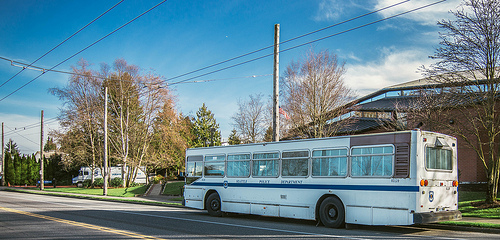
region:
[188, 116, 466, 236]
white bus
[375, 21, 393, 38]
white clouds in blue sky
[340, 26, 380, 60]
white clouds in blue sky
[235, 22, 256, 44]
white clouds in blue sky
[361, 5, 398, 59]
white clouds in blue sky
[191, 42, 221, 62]
white clouds in blue sky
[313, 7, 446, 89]
The sky is blue with some clouds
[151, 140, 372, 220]
The bus is parked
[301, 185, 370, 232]
The wheels are round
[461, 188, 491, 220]
The grass is green and short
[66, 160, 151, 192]
The truck is parked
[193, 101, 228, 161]
The tree is very tall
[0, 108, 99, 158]
The power lines are above the street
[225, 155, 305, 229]
The bus is mostly white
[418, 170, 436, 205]
The lights are off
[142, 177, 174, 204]
The walkway is concrete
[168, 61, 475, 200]
a bus on the road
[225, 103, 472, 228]
a bus on the street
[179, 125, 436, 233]
an old bus on the road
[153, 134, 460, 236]
an old bus on the street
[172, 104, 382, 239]
a white bus on the road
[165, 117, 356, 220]
a white bus on the street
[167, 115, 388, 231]
an old white bus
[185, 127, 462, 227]
a white passenger bus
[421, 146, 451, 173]
the rear window is closed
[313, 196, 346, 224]
the tire is black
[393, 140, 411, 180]
vents on the bus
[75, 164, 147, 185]
a white box truck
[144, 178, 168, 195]
a side walk by the grass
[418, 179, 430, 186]
tail lights on the bus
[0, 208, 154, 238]
a double yellow line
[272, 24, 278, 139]
a concrete pole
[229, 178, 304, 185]
blue lettering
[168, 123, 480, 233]
blue and white bus parked on the curb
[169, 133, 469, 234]
blue and white bus parked on the curb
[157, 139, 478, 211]
blue and white bus parked on the curb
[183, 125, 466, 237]
blue and white bus parked on the curb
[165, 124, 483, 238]
blue and white bus parked on the curb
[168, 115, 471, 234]
blue and white bus parked on the curb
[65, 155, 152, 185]
truck parked in the driveway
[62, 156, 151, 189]
truck parked in the driveway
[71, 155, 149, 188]
truck parked in the driveway